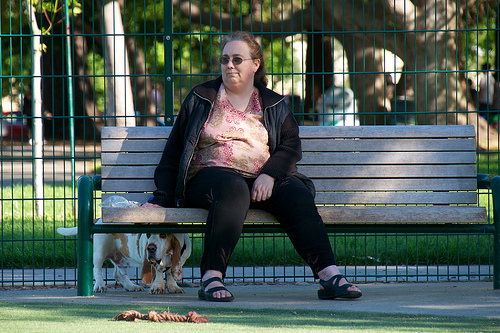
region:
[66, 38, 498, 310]
woman sitting on a bench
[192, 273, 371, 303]
black sandals on the feet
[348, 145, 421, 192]
light shiing on the bench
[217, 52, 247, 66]
sunglasses on the face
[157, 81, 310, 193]
jacket is hanging open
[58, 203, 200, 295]
brown and white dog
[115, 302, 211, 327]
dog toy on the ground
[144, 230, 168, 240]
two black eyes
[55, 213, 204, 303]
dog under the bench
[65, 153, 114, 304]
green pole on the side of the bench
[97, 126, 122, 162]
light shining on the bench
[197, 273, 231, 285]
thick black strap on the sandal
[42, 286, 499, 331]
shadows on the ground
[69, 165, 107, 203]
armrest is green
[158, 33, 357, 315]
a woman sitting on a bench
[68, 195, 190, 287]
a dogn hiding under the bench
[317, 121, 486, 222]
tan wooden slats of the bench seat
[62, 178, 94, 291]
green support post of the bench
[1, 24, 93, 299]
green chain link fence behind the bench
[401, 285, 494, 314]
grey concrete surface of the path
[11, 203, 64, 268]
gren grass of the ground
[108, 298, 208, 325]
several dead red leaves on the ground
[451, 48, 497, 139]
s boy standing next to a tree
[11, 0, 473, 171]
several trees growing behind the fence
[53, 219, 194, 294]
a dog standing beneath a bench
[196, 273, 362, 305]
woman wearing black sandals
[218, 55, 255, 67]
woman wearing sunglasses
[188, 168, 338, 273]
woman wearing black pants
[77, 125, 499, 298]
a wooden bench with green poles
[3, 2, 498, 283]
a green metal fence behind a bench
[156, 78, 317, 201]
woman wearing a black coat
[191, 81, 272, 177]
woman wearing a yellow and pink flowery shirt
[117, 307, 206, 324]
a pet toy on the grass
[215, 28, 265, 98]
the head of a woman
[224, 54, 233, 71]
the nose of a woman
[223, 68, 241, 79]
the mouth of a woman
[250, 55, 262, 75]
the ear of a woman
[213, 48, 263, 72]
a pair of sunglasses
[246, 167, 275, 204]
the hand of a woman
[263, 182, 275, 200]
the finger of a woman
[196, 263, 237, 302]
the foot of a woman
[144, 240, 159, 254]
the nose of a dog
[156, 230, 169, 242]
the eye of a dog